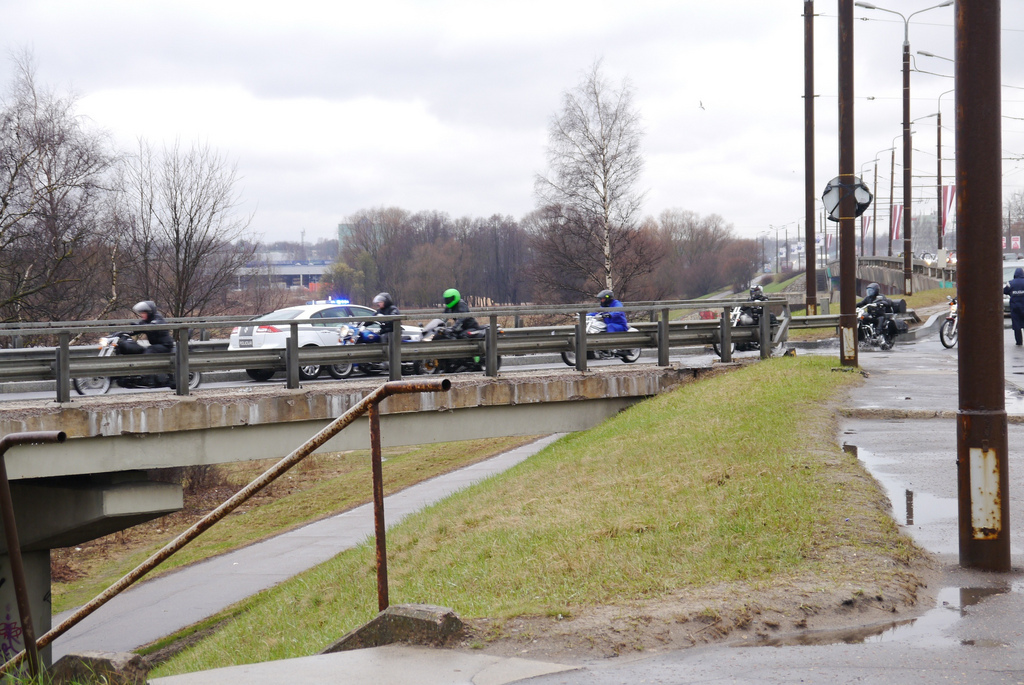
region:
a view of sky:
[186, 47, 346, 164]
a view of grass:
[578, 495, 670, 585]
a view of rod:
[334, 442, 467, 616]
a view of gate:
[123, 394, 351, 595]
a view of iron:
[240, 418, 346, 485]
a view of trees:
[501, 37, 718, 420]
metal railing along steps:
[9, 375, 453, 683]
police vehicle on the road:
[227, 294, 425, 380]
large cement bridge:
[209, 263, 339, 293]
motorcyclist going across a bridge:
[70, 296, 201, 396]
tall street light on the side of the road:
[849, 0, 955, 299]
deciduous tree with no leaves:
[524, 56, 665, 301]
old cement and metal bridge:
[0, 282, 794, 479]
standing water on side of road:
[833, 338, 1023, 681]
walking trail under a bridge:
[46, 432, 584, 661]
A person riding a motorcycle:
[414, 285, 501, 372]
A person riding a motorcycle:
[331, 291, 408, 371]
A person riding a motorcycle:
[72, 300, 199, 395]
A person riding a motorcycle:
[561, 287, 642, 367]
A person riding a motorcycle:
[710, 282, 777, 356]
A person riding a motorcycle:
[856, 279, 898, 343]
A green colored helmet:
[445, 288, 461, 309]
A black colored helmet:
[596, 288, 619, 304]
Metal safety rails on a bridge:
[2, 298, 783, 404]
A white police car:
[228, 294, 426, 378]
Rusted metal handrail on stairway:
[0, 373, 454, 675]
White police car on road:
[228, 293, 443, 379]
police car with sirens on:
[232, 285, 433, 380]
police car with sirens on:
[214, 282, 434, 375]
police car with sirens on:
[229, 288, 442, 403]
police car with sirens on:
[218, 275, 441, 374]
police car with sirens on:
[220, 275, 493, 396]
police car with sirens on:
[224, 279, 459, 374]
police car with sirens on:
[224, 277, 458, 385]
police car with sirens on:
[211, 271, 447, 380]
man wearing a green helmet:
[425, 283, 490, 359]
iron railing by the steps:
[17, 372, 457, 661]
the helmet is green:
[440, 284, 463, 310]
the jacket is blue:
[596, 300, 626, 329]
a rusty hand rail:
[7, 374, 453, 676]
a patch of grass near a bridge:
[156, 358, 904, 665]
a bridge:
[0, 334, 770, 670]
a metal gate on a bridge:
[0, 298, 793, 403]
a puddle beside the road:
[844, 429, 963, 557]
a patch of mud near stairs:
[478, 562, 924, 646]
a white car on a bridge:
[229, 301, 423, 379]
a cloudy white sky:
[3, 0, 1021, 248]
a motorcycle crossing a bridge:
[853, 289, 896, 347]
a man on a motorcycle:
[123, 296, 172, 367]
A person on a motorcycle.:
[84, 302, 205, 397]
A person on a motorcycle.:
[302, 294, 436, 368]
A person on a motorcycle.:
[404, 286, 516, 382]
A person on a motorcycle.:
[552, 286, 663, 363]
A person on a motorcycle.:
[702, 270, 797, 365]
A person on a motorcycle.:
[850, 286, 920, 350]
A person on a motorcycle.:
[947, 292, 970, 340]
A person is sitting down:
[119, 304, 183, 391]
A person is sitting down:
[356, 285, 411, 366]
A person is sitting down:
[432, 283, 484, 369]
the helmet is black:
[593, 284, 614, 303]